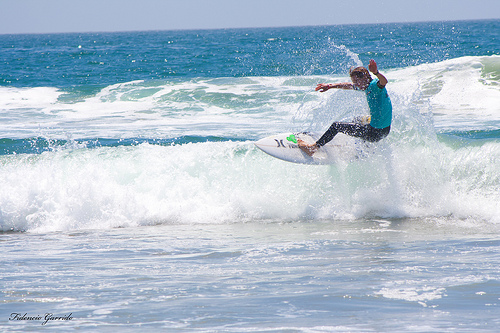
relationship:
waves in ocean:
[4, 64, 476, 216] [4, 18, 484, 324]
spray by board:
[300, 42, 428, 150] [252, 130, 349, 169]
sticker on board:
[284, 130, 305, 152] [259, 128, 352, 168]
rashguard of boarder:
[351, 79, 392, 130] [301, 56, 392, 154]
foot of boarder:
[296, 138, 316, 158] [301, 56, 392, 154]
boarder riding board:
[296, 58, 393, 156] [264, 130, 370, 167]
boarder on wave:
[296, 58, 393, 156] [4, 137, 483, 235]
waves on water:
[10, 56, 482, 239] [6, 17, 484, 327]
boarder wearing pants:
[296, 58, 393, 156] [309, 113, 388, 152]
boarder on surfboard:
[296, 58, 393, 156] [256, 130, 361, 165]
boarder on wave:
[296, 58, 393, 156] [4, 126, 483, 226]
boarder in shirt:
[296, 58, 393, 156] [348, 75, 396, 127]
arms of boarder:
[311, 58, 391, 90] [296, 58, 393, 156]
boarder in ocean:
[296, 58, 393, 156] [4, 18, 484, 324]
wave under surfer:
[4, 126, 483, 226] [294, 59, 394, 157]